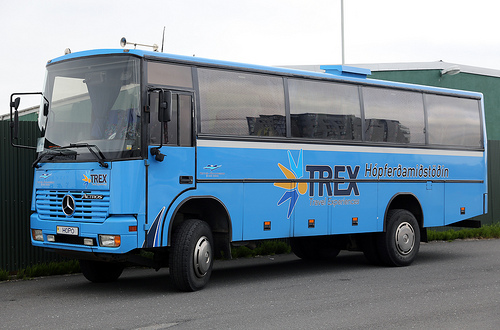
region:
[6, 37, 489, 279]
blue coach bus on road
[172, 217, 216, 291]
front tire of bus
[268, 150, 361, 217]
TREX logo on side of bus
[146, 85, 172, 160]
black side mirror of bus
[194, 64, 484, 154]
passenger windows of bus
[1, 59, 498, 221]
green and white building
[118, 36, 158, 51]
chrome horn on top of bus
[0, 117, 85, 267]
black stockade type fence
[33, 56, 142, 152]
front windshield of bus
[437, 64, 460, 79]
exterior light on building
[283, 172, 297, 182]
yellow color on bus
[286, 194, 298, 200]
dark blue color on bus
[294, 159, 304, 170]
light blue color on bus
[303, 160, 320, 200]
letter t on bus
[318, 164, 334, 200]
letter r on bus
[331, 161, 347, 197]
letter e on bus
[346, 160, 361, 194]
letter x on bus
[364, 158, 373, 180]
letter h on bus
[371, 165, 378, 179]
letter o on bus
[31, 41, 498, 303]
big blue bus on road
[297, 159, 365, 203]
TREX written on side of bus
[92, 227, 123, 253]
left front headlight of bus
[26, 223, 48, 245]
right front headlight of bus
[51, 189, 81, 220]
Mercedes logo on front of bus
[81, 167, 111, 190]
Trex written on front of bus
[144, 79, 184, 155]
Left rear view mirror on bus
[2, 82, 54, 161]
Right rear view mirror on bus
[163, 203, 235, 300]
Left front tire on blue bus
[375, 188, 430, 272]
Left rear tire on blue bus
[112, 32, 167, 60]
horn on the top of blue bus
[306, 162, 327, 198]
black letter on bus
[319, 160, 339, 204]
black letter on bus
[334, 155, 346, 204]
black letter on bus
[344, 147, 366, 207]
black letter on bus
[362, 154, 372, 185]
black letter on bus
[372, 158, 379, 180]
black letter on bus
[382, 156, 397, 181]
black letter on bus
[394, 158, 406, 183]
black letter on bus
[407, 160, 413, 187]
black letter on bus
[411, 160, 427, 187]
black letter on bus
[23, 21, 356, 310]
vBlue bus parked in road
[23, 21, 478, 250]
Blue bus parked in road